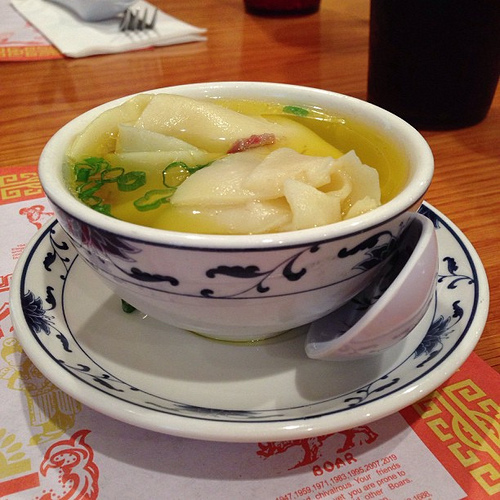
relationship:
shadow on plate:
[73, 289, 410, 401] [9, 199, 492, 445]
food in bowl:
[61, 86, 412, 234] [80, 190, 440, 390]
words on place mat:
[309, 452, 356, 474] [1, 162, 498, 497]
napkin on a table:
[7, 1, 213, 61] [0, 0, 498, 498]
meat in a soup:
[226, 132, 273, 153] [94, 117, 364, 232]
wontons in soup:
[118, 95, 377, 247] [125, 110, 346, 210]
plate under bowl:
[9, 201, 490, 442] [36, 74, 455, 341]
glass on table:
[394, 17, 484, 88] [131, 33, 329, 69]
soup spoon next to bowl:
[292, 207, 455, 384] [36, 74, 455, 341]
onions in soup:
[79, 164, 132, 196] [50, 77, 493, 362]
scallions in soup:
[83, 147, 138, 207] [45, 54, 432, 246]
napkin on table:
[7, 1, 207, 61] [98, 51, 299, 77]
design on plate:
[438, 257, 471, 368] [22, 103, 475, 455]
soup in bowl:
[125, 110, 346, 210] [36, 74, 455, 341]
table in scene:
[1, 1, 497, 381] [0, 13, 484, 460]